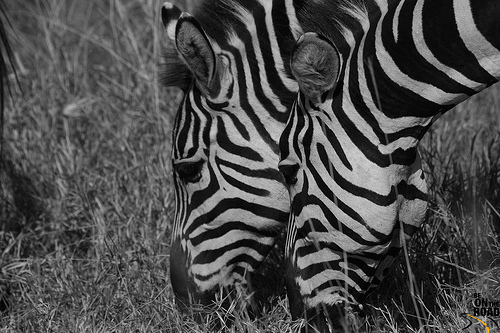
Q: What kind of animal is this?
A: Zebra.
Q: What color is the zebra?
A: Black and white.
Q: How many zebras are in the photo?
A: Two.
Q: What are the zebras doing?
A: Grazing.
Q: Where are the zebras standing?
A: Field.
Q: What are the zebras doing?
A: Eating.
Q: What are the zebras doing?
A: Grazing.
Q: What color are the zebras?
A: Black and white.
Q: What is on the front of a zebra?
A: Face.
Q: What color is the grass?
A: Black and white.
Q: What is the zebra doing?
A: Eating grass.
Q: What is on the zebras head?
A: Ears.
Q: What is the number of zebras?
A: Two.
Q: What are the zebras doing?
A: Foraging.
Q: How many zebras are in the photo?
A: Two.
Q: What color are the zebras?
A: Black and white.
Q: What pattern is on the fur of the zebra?
A: Stripes.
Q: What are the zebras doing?
A: Grazing.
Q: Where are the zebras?
A: On the grass.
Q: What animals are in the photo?
A: Zebra.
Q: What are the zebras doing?
A: Eating.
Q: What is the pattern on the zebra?
A: Stripe.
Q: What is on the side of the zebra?
A: Ear.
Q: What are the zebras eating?
A: Grass.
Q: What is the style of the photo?
A: Black and white.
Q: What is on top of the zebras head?
A: Hair.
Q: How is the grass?
A: Dry.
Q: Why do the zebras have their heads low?
A: They are grazing.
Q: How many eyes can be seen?
A: 2.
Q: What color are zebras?
A: Black and white.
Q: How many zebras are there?
A: 2.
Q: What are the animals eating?
A: Grass.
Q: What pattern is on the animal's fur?
A: Stripes.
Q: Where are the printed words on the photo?
A: Bottom right.